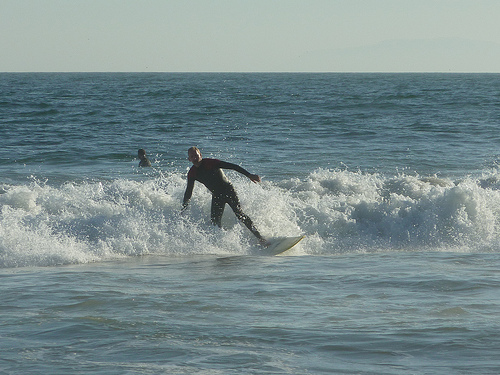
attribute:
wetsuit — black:
[179, 156, 267, 251]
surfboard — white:
[239, 230, 308, 260]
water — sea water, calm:
[1, 70, 498, 373]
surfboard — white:
[271, 234, 303, 254]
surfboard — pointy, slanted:
[262, 234, 308, 259]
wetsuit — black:
[191, 160, 235, 212]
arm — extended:
[183, 171, 195, 213]